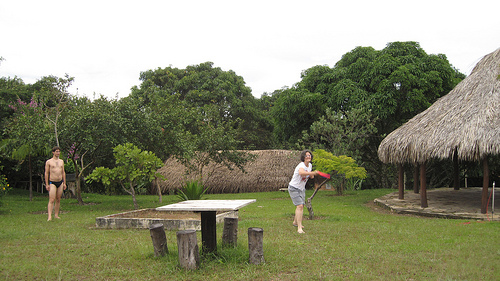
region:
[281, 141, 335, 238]
The man with the frisbee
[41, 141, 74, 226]
The man in a speedo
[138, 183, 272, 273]
The table with stumps around it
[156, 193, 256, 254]
The white outdoor table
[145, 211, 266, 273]
The stumps around the table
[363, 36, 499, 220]
The circular straw hut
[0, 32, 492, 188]
Green trees behind the people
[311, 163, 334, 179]
The red frisbee being thrown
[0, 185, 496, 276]
Green grass covering the ground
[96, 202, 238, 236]
The square wood box in the grass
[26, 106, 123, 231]
the man is naked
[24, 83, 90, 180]
the man is naked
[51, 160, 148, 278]
the man is naked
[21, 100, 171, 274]
the man is naked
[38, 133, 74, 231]
a man in a bathing suit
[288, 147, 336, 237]
a person throwing a frisbee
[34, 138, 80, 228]
a man wearing a speedo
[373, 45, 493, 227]
a grass-roofed hut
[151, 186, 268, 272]
picnic table with logs for stools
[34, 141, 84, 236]
a nearly nude man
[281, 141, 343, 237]
a person throwing a red frisbee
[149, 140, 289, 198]
the grass roof of a hut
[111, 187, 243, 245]
a concrete planter behind a picnic table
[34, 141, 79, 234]
guy in a black speedo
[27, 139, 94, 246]
A man in a spedo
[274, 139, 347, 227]
A woman throwing a frisbee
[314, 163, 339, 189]
a red frisbee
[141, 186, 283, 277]
a white table with wood stumps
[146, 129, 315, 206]
A straw rectangular roof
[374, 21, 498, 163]
a straw round roof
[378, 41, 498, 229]
a hut with a straw roof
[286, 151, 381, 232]
Small tree behind woman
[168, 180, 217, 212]
A green plant just beyond table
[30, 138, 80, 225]
a man is standing in the grass